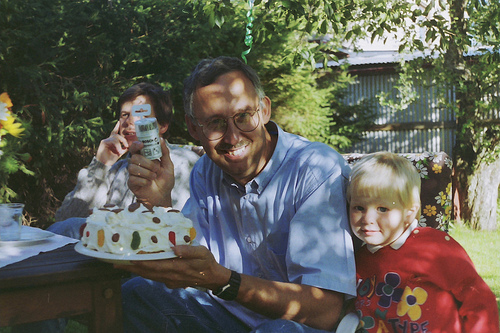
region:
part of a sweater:
[437, 280, 443, 291]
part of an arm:
[292, 268, 307, 300]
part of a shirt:
[298, 243, 305, 263]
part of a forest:
[300, 105, 314, 139]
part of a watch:
[229, 276, 236, 291]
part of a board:
[405, 114, 415, 134]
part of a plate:
[130, 255, 141, 270]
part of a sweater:
[390, 245, 402, 295]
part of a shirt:
[306, 230, 319, 252]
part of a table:
[60, 257, 91, 305]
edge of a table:
[104, 275, 113, 293]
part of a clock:
[231, 286, 235, 292]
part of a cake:
[145, 240, 155, 250]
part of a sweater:
[443, 235, 458, 257]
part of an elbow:
[317, 159, 325, 171]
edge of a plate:
[151, 244, 156, 253]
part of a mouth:
[240, 143, 245, 156]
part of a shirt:
[336, 242, 342, 249]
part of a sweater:
[443, 256, 457, 268]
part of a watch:
[229, 294, 236, 305]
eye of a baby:
[374, 198, 396, 215]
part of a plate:
[116, 250, 118, 254]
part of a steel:
[390, 88, 400, 100]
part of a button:
[241, 222, 255, 253]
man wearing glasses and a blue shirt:
[187, 58, 346, 308]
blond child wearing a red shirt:
[347, 151, 475, 329]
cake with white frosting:
[78, 205, 197, 261]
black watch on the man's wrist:
[214, 269, 242, 301]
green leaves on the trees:
[0, 1, 177, 71]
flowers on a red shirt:
[357, 276, 428, 317]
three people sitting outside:
[85, 61, 477, 328]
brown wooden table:
[5, 268, 115, 314]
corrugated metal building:
[355, 68, 440, 144]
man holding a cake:
[84, 61, 318, 327]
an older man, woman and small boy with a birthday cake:
[73, 56, 460, 322]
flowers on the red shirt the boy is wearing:
[361, 270, 437, 330]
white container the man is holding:
[131, 101, 168, 163]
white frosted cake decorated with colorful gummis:
[70, 198, 200, 261]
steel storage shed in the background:
[324, 62, 497, 147]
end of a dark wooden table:
[2, 263, 124, 318]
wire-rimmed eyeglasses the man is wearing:
[200, 99, 267, 139]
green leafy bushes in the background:
[5, 5, 96, 147]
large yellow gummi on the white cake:
[95, 226, 110, 248]